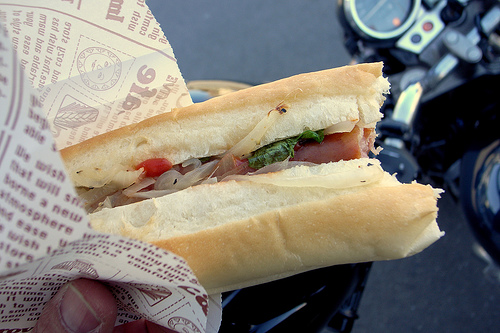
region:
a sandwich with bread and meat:
[76, 67, 464, 277]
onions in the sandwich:
[124, 153, 212, 205]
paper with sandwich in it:
[119, 243, 220, 324]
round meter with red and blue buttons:
[352, 0, 437, 45]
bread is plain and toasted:
[197, 225, 424, 285]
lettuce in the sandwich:
[254, 127, 316, 162]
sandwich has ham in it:
[310, 132, 375, 165]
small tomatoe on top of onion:
[128, 159, 184, 178]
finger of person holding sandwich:
[44, 272, 157, 331]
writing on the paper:
[80, 247, 190, 289]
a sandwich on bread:
[44, 57, 458, 294]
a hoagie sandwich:
[57, 41, 472, 283]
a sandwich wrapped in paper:
[3, 2, 469, 327]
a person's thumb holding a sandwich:
[35, 279, 122, 332]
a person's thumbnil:
[55, 286, 105, 331]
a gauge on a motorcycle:
[343, 1, 421, 39]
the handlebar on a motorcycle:
[244, 111, 431, 332]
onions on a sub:
[105, 169, 219, 191]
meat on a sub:
[278, 119, 388, 171]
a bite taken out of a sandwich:
[359, 62, 453, 232]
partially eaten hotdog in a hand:
[63, 59, 460, 299]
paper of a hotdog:
[0, 69, 71, 274]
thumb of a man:
[28, 267, 131, 331]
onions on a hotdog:
[132, 162, 218, 195]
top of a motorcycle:
[336, 3, 496, 241]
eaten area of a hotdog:
[347, 56, 457, 253]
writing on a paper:
[5, 137, 50, 228]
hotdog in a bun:
[305, 129, 377, 161]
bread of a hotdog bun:
[192, 199, 369, 245]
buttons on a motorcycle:
[404, 9, 440, 51]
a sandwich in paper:
[62, 67, 442, 272]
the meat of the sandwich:
[287, 122, 377, 164]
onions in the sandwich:
[109, 102, 291, 189]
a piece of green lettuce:
[246, 133, 323, 165]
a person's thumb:
[28, 270, 128, 331]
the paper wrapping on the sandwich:
[0, 5, 225, 327]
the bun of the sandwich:
[52, 62, 379, 185]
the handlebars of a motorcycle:
[351, 0, 498, 162]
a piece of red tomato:
[133, 158, 179, 176]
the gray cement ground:
[144, 0, 494, 330]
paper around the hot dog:
[3, 8, 186, 318]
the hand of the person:
[47, 288, 152, 329]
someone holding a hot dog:
[30, 43, 415, 328]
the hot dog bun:
[106, 195, 414, 249]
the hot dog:
[293, 130, 374, 167]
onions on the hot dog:
[148, 164, 199, 178]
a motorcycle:
[325, 3, 495, 214]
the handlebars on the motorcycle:
[391, 41, 438, 181]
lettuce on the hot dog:
[248, 140, 307, 155]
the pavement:
[383, 264, 440, 304]